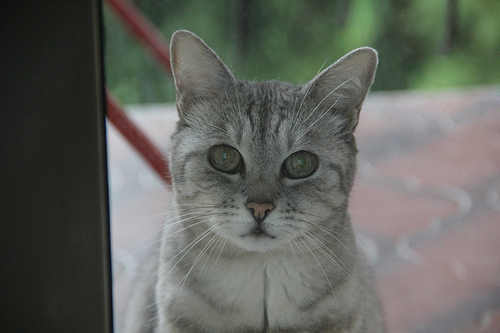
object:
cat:
[120, 29, 380, 332]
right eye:
[207, 141, 243, 176]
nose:
[248, 198, 274, 220]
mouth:
[235, 224, 278, 240]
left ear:
[299, 45, 379, 120]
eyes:
[280, 149, 320, 180]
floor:
[108, 84, 499, 332]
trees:
[102, 1, 498, 104]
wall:
[1, 0, 117, 332]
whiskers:
[280, 209, 365, 305]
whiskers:
[122, 201, 234, 310]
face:
[194, 112, 331, 249]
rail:
[100, 99, 172, 186]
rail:
[98, 1, 163, 73]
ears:
[167, 28, 244, 100]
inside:
[315, 68, 372, 108]